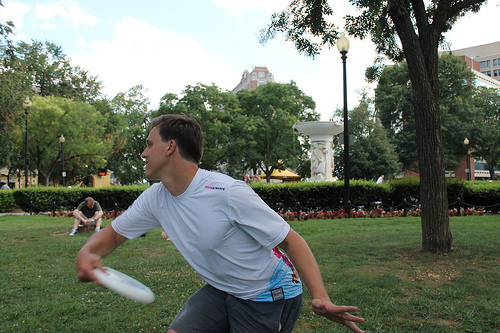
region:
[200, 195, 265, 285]
man wearing white color tees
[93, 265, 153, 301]
man holding frisbee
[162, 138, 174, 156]
ear of the man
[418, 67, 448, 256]
wooden trunk of the tree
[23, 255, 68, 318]
green color grasses on ground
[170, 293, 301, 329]
man wearing grey color shorts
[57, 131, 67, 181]
black pole with fixture of lamp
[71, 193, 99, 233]
man sitting and relaxing at background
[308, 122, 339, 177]
white sculptor visible at background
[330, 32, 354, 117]
it is a lamp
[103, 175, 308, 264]
man wearing white shirt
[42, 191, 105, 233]
man seating on the ground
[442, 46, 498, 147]
it is a building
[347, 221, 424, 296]
green color grass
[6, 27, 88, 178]
it is a big tree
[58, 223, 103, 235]
man wearing white shoe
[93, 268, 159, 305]
The frisbee in the guy's hand.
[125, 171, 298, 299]
The white shirt the guy is wearing.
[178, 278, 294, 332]
The gray shorts the guy is wearing.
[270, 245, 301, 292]
The red design on the guy's shirt.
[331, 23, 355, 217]
The lamp post on the right.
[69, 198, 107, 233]
The guy sitting down.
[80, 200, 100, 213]
The green shirt the guy is wearing.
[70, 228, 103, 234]
The sneakers the guy is wearing.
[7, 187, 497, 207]
The hedges behind the guy sitting down.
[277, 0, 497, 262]
The tree behind the guy throwing the frisbee.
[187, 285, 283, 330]
man has grey shorts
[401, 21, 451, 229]
brown tree behind man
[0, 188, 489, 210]
row of green bushes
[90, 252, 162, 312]
man holds white frisbee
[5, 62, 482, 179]
green trees behind bushes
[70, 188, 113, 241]
man sits on grass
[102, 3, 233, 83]
blue and white sky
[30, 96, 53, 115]
green leaf on tree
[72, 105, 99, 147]
green leaf on tree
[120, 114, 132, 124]
green leaf on tree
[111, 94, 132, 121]
green leaf on tree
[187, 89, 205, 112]
green leaf on tree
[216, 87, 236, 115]
green leaf on tree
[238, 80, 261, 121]
green leaf on tree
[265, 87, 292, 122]
green leaf on tree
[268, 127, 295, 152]
green leaf on tree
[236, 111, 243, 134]
green leaf on tree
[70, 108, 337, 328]
man throwing a white frisbee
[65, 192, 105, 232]
man is sitting on the ground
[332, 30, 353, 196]
lamp on top of a black pole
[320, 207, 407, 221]
row of flowers in front of the bushes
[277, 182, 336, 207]
green bushes in back of the flowers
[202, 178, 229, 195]
red and black logo on the shirt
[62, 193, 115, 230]
man is wearing a green shirt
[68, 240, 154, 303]
white frisbee in the hand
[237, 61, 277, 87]
top of a building above the trees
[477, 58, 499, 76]
windows on the building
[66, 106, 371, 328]
Man throwing a white frisbie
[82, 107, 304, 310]
Man wearing a white shirt.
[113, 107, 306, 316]
Man wearing grey shorts.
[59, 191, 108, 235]
Man looking at the ground.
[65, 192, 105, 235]
Man wearing a green shirt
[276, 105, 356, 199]
Large fountain in the park.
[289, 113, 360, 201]
White fountain behind the hedges.